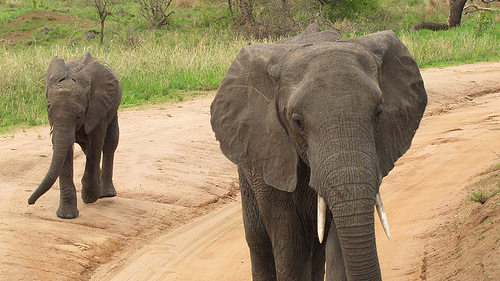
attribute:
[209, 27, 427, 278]
elephant — walking, strong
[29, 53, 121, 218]
elephant — small, young, walking, strong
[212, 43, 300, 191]
right ear — huge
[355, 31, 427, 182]
left ear — huge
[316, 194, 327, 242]
tusk — impressive, white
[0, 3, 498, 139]
grass — green, brown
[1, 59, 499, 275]
pathway — dirty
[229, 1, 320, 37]
bush — dried, small